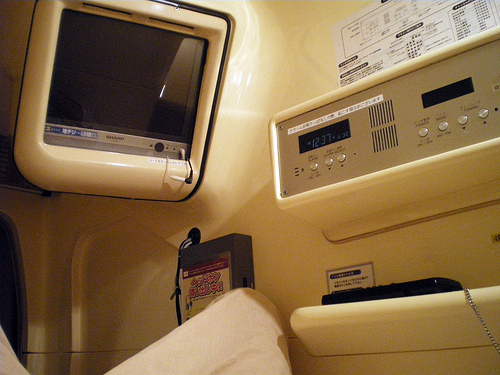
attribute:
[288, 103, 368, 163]
screen — black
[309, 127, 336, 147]
lights — blue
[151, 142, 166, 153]
sensor — black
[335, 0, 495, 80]
sign — black and white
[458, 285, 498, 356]
cord — gray, curly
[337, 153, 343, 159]
button — silver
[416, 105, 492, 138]
four buttons — silver, round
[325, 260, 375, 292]
sign — white, blue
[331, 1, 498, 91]
sign — black and white, on wall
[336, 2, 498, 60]
diagram — white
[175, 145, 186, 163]
button — to adjust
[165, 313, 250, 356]
pillow — white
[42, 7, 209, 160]
screen — black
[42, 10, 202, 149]
screen — black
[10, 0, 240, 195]
monitor — white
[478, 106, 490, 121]
button — silver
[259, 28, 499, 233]
device — electronic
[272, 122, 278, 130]
screw — metal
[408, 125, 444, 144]
button — silver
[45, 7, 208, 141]
screen — black